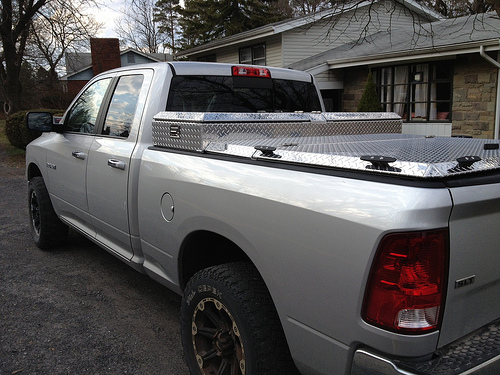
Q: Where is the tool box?
A: Behind cab.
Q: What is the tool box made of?
A: Aluminum.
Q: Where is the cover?
A: Truck bed.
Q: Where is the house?
A: Right of truck.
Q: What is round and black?
A: Tires.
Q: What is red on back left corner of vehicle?
A: Tail light.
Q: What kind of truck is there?
A: A gray truck.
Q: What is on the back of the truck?
A: A light.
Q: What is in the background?
A: A house.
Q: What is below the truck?
A: Street.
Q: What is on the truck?
A: Tires.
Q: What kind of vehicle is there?
A: A truck.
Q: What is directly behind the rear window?
A: Tool box.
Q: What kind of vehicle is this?
A: Truck.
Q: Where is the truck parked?
A: In front of the house.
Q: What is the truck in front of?
A: A house.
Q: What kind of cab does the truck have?
A: Extended cab.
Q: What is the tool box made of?
A: Metal.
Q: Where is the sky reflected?
A: In the driver side windows.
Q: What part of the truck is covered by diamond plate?
A: Tool box and trunk cover.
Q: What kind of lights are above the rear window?
A: Red brake lights.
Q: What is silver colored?
A: Pick up truck.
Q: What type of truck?
A: Pick up.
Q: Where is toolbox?
A: On truck.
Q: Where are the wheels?
A: On truck.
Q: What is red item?
A: Tail lights.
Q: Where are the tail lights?
A: On truck.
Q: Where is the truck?
A: Driveway.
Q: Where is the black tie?
A: On truck.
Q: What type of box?
A: Tool.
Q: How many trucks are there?
A: One.